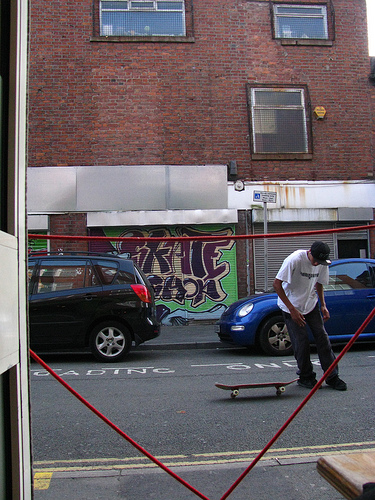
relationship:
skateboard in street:
[215, 377, 301, 400] [33, 347, 363, 465]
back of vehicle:
[48, 256, 159, 356] [25, 252, 166, 364]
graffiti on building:
[98, 225, 237, 321] [27, 1, 374, 341]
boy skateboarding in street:
[271, 240, 347, 391] [31, 342, 374, 499]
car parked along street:
[30, 252, 161, 361] [31, 342, 374, 499]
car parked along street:
[217, 255, 374, 357] [31, 342, 374, 499]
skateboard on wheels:
[215, 377, 301, 400] [224, 389, 286, 397]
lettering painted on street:
[33, 356, 331, 374] [31, 342, 374, 499]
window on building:
[247, 83, 315, 160] [70, 67, 189, 147]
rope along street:
[133, 231, 355, 256] [148, 383, 240, 437]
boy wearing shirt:
[271, 240, 347, 391] [281, 260, 335, 312]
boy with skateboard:
[274, 235, 352, 388] [215, 368, 297, 392]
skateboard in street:
[215, 368, 297, 392] [158, 400, 192, 431]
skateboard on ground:
[215, 377, 301, 400] [172, 430, 240, 444]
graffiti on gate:
[88, 225, 241, 327] [155, 258, 230, 300]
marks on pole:
[254, 190, 279, 204] [260, 214, 267, 278]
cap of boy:
[311, 243, 328, 263] [281, 242, 346, 389]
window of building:
[239, 87, 317, 161] [54, 62, 193, 128]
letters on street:
[106, 360, 165, 384] [104, 385, 151, 398]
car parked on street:
[28, 249, 161, 362] [157, 346, 174, 358]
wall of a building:
[99, 126, 131, 145] [35, 55, 176, 134]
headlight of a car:
[231, 302, 262, 316] [234, 258, 363, 341]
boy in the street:
[271, 240, 347, 391] [175, 394, 228, 436]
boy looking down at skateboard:
[271, 240, 347, 391] [215, 377, 301, 400]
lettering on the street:
[84, 359, 168, 382] [142, 396, 220, 432]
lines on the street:
[205, 447, 234, 464] [146, 394, 221, 438]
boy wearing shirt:
[271, 240, 347, 391] [284, 261, 329, 313]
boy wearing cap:
[271, 240, 347, 391] [314, 235, 326, 257]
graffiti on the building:
[88, 225, 241, 327] [108, 68, 194, 138]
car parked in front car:
[28, 249, 161, 362] [262, 251, 362, 333]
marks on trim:
[271, 188, 298, 196] [273, 180, 363, 217]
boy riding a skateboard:
[271, 240, 347, 391] [211, 379, 294, 396]